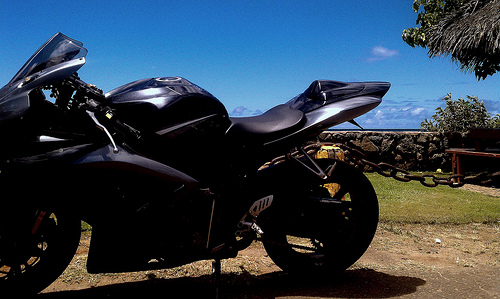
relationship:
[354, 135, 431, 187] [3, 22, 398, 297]
chain behind bike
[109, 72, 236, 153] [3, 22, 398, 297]
gas tank on bike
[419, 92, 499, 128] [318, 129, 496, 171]
bush by wall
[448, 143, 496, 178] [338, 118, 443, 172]
table by wall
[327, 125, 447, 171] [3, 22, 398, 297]
wall behind bike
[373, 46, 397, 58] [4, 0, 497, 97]
cloud in sky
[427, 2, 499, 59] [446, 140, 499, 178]
thatch roof over table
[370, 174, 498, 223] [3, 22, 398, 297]
grass behind bike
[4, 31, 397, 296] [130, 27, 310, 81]
motorcycle parked outside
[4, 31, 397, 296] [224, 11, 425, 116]
motorcycle parked outside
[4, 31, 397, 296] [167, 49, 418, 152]
motorcycle parked outside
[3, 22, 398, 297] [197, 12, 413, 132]
bike parked outside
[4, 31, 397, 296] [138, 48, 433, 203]
motorcycle parked outside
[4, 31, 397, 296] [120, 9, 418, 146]
motorcycle parked outside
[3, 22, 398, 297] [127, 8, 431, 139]
bike parked outside